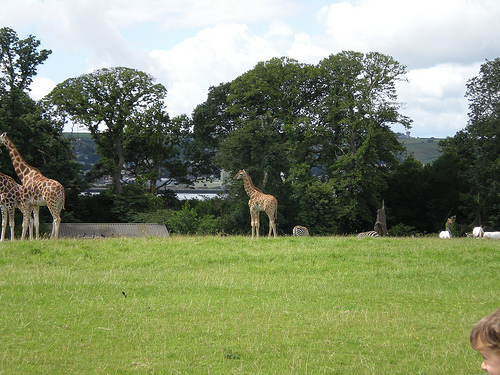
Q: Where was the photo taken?
A: It was taken at the field.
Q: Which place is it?
A: It is a field.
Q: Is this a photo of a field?
A: Yes, it is showing a field.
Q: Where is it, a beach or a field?
A: It is a field.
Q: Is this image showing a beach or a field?
A: It is showing a field.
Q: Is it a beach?
A: No, it is a field.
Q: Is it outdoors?
A: Yes, it is outdoors.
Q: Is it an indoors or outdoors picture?
A: It is outdoors.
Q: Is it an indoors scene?
A: No, it is outdoors.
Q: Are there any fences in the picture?
A: No, there are no fences.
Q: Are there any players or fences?
A: No, there are no fences or players.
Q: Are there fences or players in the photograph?
A: No, there are no fences or players.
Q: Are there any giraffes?
A: Yes, there is a giraffe.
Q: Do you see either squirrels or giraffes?
A: Yes, there is a giraffe.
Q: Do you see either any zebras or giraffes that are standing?
A: Yes, the giraffe is standing.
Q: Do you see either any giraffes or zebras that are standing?
A: Yes, the giraffe is standing.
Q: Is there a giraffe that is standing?
A: Yes, there is a giraffe that is standing.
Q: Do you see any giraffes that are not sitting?
A: Yes, there is a giraffe that is standing .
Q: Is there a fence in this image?
A: No, there are no fences.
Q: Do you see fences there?
A: No, there are no fences.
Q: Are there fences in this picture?
A: No, there are no fences.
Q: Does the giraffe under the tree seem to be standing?
A: Yes, the giraffe is standing.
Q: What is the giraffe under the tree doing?
A: The giraffe is standing.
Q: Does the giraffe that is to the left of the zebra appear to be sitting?
A: No, the giraffe is standing.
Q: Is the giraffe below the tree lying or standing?
A: The giraffe is standing.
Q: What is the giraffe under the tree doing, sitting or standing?
A: The giraffe is standing.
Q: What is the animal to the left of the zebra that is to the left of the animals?
A: The animal is a giraffe.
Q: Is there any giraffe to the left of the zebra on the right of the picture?
A: Yes, there is a giraffe to the left of the zebra.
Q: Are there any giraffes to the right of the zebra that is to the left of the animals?
A: No, the giraffe is to the left of the zebra.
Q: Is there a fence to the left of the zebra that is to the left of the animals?
A: No, there is a giraffe to the left of the zebra.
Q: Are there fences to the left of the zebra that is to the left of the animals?
A: No, there is a giraffe to the left of the zebra.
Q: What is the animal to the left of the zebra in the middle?
A: The animal is a giraffe.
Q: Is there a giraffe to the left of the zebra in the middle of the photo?
A: Yes, there is a giraffe to the left of the zebra.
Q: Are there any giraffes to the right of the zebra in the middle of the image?
A: No, the giraffe is to the left of the zebra.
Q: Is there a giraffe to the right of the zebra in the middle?
A: No, the giraffe is to the left of the zebra.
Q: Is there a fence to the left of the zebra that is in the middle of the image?
A: No, there is a giraffe to the left of the zebra.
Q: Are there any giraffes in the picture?
A: Yes, there is a giraffe.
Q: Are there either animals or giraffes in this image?
A: Yes, there is a giraffe.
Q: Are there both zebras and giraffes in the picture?
A: Yes, there are both a giraffe and a zebra.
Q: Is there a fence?
A: No, there are no fences.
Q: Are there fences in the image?
A: No, there are no fences.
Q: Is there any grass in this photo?
A: Yes, there is grass.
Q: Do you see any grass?
A: Yes, there is grass.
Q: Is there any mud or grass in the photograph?
A: Yes, there is grass.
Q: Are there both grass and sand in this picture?
A: No, there is grass but no sand.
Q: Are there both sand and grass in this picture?
A: No, there is grass but no sand.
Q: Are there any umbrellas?
A: No, there are no umbrellas.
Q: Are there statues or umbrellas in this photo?
A: No, there are no umbrellas or statues.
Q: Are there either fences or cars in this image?
A: No, there are no cars or fences.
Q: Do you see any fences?
A: No, there are no fences.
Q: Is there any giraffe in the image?
A: Yes, there is a giraffe.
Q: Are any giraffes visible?
A: Yes, there is a giraffe.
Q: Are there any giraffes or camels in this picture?
A: Yes, there is a giraffe.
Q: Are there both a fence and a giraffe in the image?
A: No, there is a giraffe but no fences.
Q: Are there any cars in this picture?
A: No, there are no cars.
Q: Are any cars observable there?
A: No, there are no cars.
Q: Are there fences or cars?
A: No, there are no cars or fences.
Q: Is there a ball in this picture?
A: No, there are no balls.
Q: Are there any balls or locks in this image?
A: No, there are no balls or locks.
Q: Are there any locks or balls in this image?
A: No, there are no balls or locks.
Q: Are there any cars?
A: No, there are no cars.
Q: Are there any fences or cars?
A: No, there are no cars or fences.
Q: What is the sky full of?
A: The sky is full of clouds.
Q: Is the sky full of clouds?
A: Yes, the sky is full of clouds.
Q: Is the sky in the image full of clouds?
A: Yes, the sky is full of clouds.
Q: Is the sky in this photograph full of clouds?
A: Yes, the sky is full of clouds.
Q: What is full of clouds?
A: The sky is full of clouds.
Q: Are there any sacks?
A: No, there are no sacks.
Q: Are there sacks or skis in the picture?
A: No, there are no sacks or skis.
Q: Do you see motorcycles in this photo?
A: No, there are no motorcycles.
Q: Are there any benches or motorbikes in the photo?
A: No, there are no motorbikes or benches.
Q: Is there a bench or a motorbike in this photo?
A: No, there are no motorcycles or benches.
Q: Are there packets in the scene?
A: No, there are no packets.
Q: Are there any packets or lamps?
A: No, there are no packets or lamps.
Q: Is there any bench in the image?
A: No, there are no benches.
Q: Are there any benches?
A: No, there are no benches.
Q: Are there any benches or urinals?
A: No, there are no benches or urinals.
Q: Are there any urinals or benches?
A: No, there are no benches or urinals.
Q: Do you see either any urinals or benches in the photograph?
A: No, there are no benches or urinals.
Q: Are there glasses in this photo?
A: No, there are no glasses.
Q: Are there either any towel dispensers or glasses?
A: No, there are no glasses or towel dispensers.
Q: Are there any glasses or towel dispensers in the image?
A: No, there are no glasses or towel dispensers.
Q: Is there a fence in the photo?
A: No, there are no fences.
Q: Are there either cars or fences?
A: No, there are no fences or cars.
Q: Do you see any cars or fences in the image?
A: No, there are no fences or cars.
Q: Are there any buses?
A: No, there are no buses.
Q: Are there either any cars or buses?
A: No, there are no buses or cars.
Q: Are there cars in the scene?
A: No, there are no cars.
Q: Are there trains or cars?
A: No, there are no cars or trains.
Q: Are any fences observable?
A: No, there are no fences.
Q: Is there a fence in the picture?
A: No, there are no fences.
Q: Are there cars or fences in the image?
A: No, there are no fences or cars.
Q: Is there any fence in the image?
A: No, there are no fences.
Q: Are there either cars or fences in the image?
A: No, there are no fences or cars.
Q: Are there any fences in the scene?
A: No, there are no fences.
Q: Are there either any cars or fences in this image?
A: No, there are no fences or cars.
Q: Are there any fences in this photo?
A: No, there are no fences.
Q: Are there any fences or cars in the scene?
A: No, there are no fences or cars.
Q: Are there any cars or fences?
A: No, there are no fences or cars.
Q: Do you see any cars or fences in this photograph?
A: No, there are no fences or cars.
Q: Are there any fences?
A: No, there are no fences.